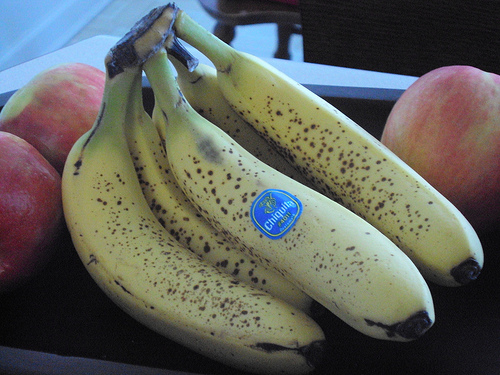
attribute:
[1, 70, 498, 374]
surface — black, stone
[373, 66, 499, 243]
apple — pink, red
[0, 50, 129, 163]
apple — pink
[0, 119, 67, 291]
apple — pink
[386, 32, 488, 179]
apple — red, green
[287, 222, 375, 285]
banana peel — yellow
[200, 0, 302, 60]
chair — brown, wooden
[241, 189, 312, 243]
label — blue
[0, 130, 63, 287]
apple — red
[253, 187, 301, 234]
sticker — blue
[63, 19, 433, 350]
bananas — bruised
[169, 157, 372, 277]
sticker — blue 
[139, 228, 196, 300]
spots — brown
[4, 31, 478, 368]
bin — wooden